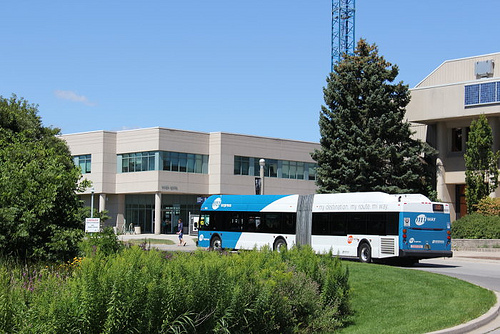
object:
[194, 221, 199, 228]
sideview mirror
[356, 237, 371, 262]
tire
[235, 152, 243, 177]
window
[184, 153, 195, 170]
window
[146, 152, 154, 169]
window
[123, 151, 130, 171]
window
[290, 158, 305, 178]
window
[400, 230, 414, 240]
lights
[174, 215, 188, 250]
pedestrian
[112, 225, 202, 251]
sidewalk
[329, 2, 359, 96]
tower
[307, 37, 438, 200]
tree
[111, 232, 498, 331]
street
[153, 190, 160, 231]
support column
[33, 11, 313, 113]
sky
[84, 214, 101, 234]
white sign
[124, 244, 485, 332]
grass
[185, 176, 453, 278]
bus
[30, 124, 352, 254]
building